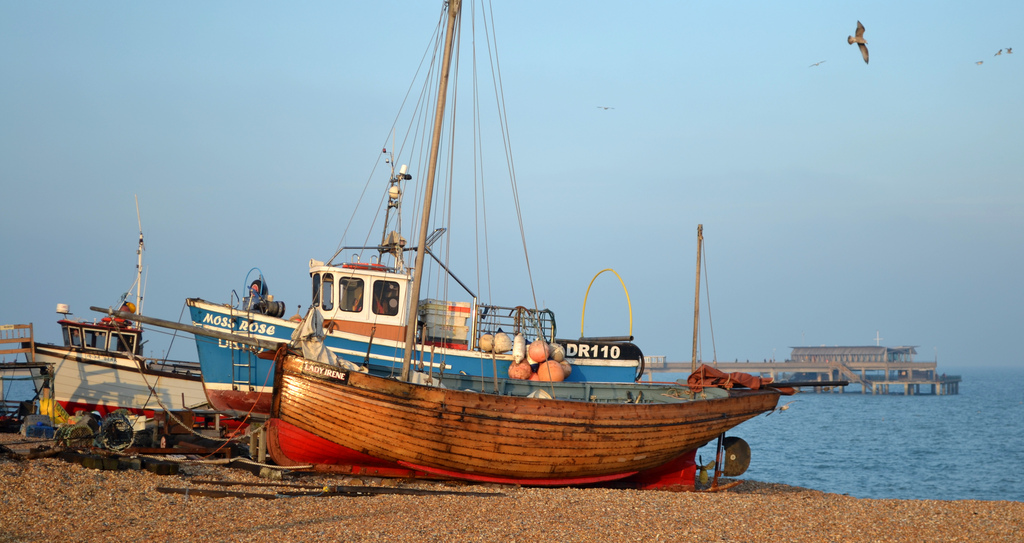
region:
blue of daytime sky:
[3, 3, 1021, 359]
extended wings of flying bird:
[847, 18, 870, 66]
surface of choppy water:
[711, 372, 1022, 500]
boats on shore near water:
[4, 1, 1022, 540]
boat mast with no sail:
[302, 0, 549, 383]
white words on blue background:
[200, 310, 277, 339]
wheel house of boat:
[307, 260, 410, 325]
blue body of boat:
[191, 299, 640, 417]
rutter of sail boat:
[716, 433, 749, 476]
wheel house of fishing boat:
[57, 319, 140, 357]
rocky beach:
[7, 416, 1017, 540]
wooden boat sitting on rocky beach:
[242, 334, 799, 493]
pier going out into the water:
[623, 337, 968, 402]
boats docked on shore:
[36, 19, 793, 479]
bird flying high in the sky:
[842, 10, 878, 65]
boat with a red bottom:
[279, 0, 789, 506]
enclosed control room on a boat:
[302, 249, 421, 357]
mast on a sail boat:
[394, 3, 474, 396]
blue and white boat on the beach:
[178, 255, 649, 433]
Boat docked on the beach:
[249, 297, 818, 500]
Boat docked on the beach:
[12, 271, 199, 440]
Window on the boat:
[303, 268, 399, 316]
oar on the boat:
[389, 21, 508, 353]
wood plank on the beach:
[154, 471, 505, 513]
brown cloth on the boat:
[678, 351, 789, 405]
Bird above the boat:
[836, 13, 888, 72]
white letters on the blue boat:
[186, 301, 291, 349]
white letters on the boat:
[555, 331, 623, 364]